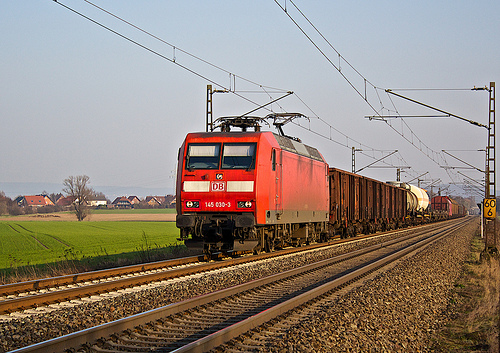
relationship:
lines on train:
[142, 15, 419, 127] [175, 130, 468, 230]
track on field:
[9, 213, 70, 248] [12, 197, 161, 254]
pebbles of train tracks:
[262, 225, 479, 348] [0, 207, 480, 351]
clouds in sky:
[73, 145, 129, 157] [44, 80, 147, 118]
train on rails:
[172, 110, 467, 264] [0, 216, 475, 351]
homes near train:
[0, 192, 177, 216] [172, 110, 467, 264]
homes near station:
[0, 192, 177, 216] [406, 75, 484, 317]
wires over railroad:
[69, 5, 480, 196] [141, 257, 328, 328]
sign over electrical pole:
[483, 198, 496, 219] [272, 78, 495, 235]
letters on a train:
[208, 183, 223, 192] [165, 144, 382, 252]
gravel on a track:
[170, 305, 398, 353] [126, 242, 276, 347]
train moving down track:
[177, 117, 461, 276] [129, 295, 362, 353]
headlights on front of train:
[175, 194, 254, 209] [165, 148, 355, 246]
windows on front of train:
[185, 116, 256, 174] [171, 116, 472, 250]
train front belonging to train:
[178, 130, 257, 212] [172, 110, 467, 264]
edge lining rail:
[205, 208, 476, 351] [4, 212, 476, 351]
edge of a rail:
[268, 287, 307, 324] [142, 229, 372, 351]